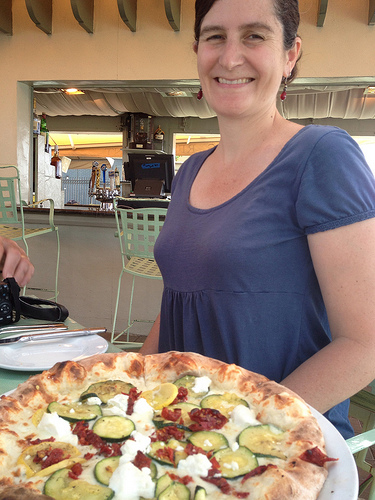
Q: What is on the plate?
A: Pizza.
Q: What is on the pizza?
A: Zucchini.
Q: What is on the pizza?
A: Tomato.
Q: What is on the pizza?
A: Squash.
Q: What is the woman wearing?
A: Shirt.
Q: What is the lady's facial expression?
A: Smile.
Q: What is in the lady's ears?
A: Earrings.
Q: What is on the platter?
A: Pizza.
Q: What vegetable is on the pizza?
A: Squash.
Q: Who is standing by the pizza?
A: Happy lady.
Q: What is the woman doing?
A: Smiling.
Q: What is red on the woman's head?
A: Earrings.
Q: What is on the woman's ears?
A: Earrings.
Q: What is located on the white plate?
A: Pizza.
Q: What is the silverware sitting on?
A: Plate.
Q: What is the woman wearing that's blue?
A: Dress.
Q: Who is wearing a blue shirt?
A: The woman.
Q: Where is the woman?
A: In a restaurant.